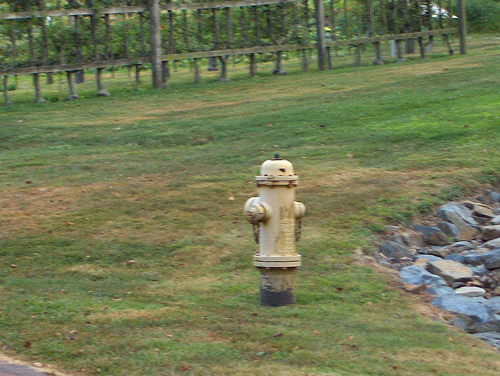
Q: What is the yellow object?
A: Fire Hydrant.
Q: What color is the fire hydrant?
A: Yellow.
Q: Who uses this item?
A: Firefighters.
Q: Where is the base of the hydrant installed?
A: Into the ground.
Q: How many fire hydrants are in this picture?
A: One.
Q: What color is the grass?
A: Green.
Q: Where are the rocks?
A: Right side.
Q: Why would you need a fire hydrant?
A: In case of a fire.